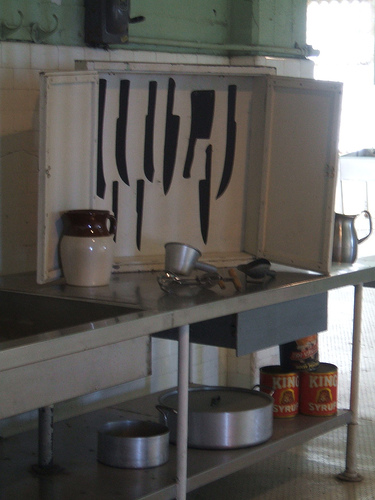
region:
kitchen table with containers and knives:
[9, 11, 368, 485]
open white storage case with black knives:
[26, 52, 343, 286]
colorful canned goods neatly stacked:
[255, 332, 343, 422]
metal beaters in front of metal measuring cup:
[153, 236, 242, 297]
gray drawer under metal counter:
[152, 279, 330, 358]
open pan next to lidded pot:
[92, 380, 275, 472]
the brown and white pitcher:
[59, 210, 115, 287]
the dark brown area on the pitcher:
[58, 209, 116, 286]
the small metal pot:
[97, 418, 169, 468]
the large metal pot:
[155, 382, 275, 447]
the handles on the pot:
[156, 383, 276, 448]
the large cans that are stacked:
[259, 333, 337, 419]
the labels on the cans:
[259, 332, 338, 418]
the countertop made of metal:
[1, 247, 373, 498]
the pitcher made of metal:
[334, 208, 373, 263]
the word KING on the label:
[259, 364, 299, 419]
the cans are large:
[259, 332, 338, 416]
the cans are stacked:
[259, 332, 336, 418]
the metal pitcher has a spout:
[334, 210, 372, 265]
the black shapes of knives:
[93, 78, 238, 251]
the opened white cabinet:
[35, 60, 343, 285]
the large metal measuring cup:
[163, 241, 216, 276]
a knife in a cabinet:
[222, 81, 262, 198]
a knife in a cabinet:
[196, 144, 213, 242]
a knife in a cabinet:
[182, 87, 208, 182]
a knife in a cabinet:
[162, 76, 177, 192]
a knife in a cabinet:
[138, 69, 160, 184]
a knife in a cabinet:
[119, 81, 137, 189]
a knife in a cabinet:
[111, 183, 129, 244]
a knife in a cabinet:
[96, 85, 112, 194]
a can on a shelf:
[297, 365, 333, 419]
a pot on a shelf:
[167, 367, 289, 490]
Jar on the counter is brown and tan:
[55, 200, 123, 292]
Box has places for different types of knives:
[30, 37, 363, 285]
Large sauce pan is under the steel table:
[159, 369, 291, 452]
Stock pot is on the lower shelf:
[85, 400, 180, 486]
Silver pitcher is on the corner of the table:
[314, 190, 374, 284]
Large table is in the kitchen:
[23, 209, 373, 497]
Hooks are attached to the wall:
[5, 9, 81, 74]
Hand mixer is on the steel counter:
[147, 255, 257, 312]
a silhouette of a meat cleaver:
[182, 82, 228, 195]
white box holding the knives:
[35, 59, 344, 280]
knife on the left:
[93, 75, 100, 199]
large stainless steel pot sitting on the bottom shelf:
[210, 393, 270, 449]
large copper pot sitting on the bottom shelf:
[256, 360, 332, 416]